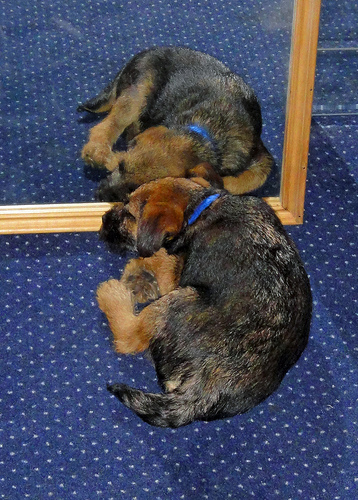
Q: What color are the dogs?
A: Black and brown.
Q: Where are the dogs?
A: On the carpet.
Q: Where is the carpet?
A: Under the dogs.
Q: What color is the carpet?
A: Blue and white.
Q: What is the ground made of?
A: Carpet.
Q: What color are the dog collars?
A: Blue.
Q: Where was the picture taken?
A: Inside a building.